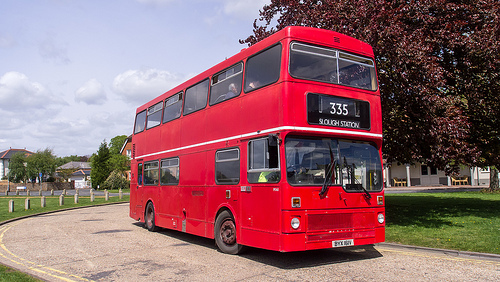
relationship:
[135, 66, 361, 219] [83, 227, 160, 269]
bus on street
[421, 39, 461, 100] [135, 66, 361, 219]
tree near bus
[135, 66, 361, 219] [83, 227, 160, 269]
bus in street